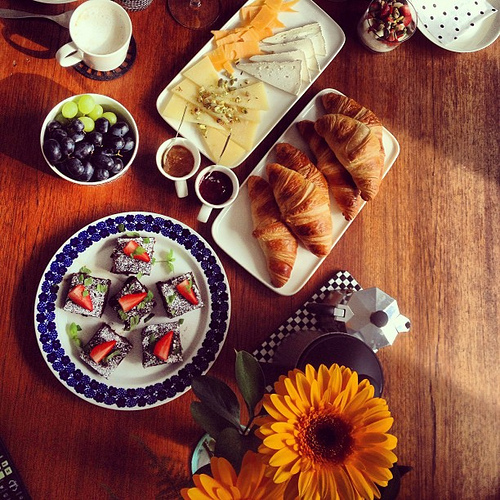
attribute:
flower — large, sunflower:
[256, 356, 398, 499]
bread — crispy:
[243, 176, 299, 288]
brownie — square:
[113, 236, 155, 273]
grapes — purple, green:
[47, 95, 134, 181]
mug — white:
[70, 2, 134, 72]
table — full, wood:
[400, 47, 500, 499]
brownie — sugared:
[81, 325, 133, 380]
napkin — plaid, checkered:
[251, 306, 308, 361]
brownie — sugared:
[157, 281, 185, 317]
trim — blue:
[37, 272, 59, 345]